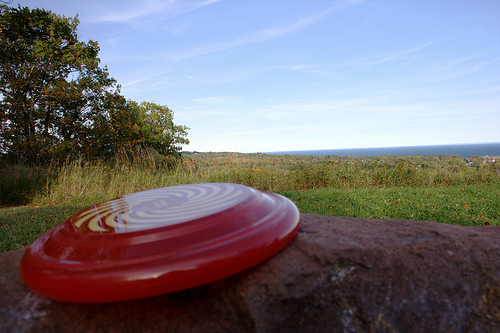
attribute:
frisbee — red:
[108, 184, 245, 259]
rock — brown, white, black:
[343, 240, 454, 315]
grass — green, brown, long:
[367, 183, 445, 219]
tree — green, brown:
[38, 35, 97, 125]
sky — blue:
[221, 8, 370, 81]